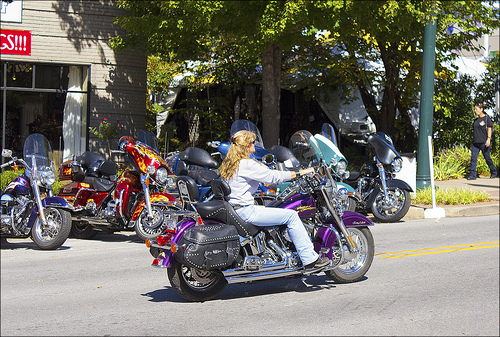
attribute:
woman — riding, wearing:
[219, 128, 292, 218]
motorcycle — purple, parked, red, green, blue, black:
[118, 122, 370, 299]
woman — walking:
[460, 104, 488, 170]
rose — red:
[87, 104, 124, 144]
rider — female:
[241, 147, 283, 192]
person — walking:
[447, 92, 495, 188]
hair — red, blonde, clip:
[217, 131, 253, 161]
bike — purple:
[297, 208, 402, 291]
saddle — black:
[190, 186, 224, 238]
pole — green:
[368, 36, 473, 214]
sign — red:
[0, 26, 41, 63]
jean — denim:
[250, 208, 316, 261]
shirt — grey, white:
[206, 158, 276, 214]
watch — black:
[288, 159, 314, 184]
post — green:
[398, 77, 458, 166]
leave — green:
[283, 13, 344, 71]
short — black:
[460, 142, 495, 177]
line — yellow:
[382, 209, 480, 297]